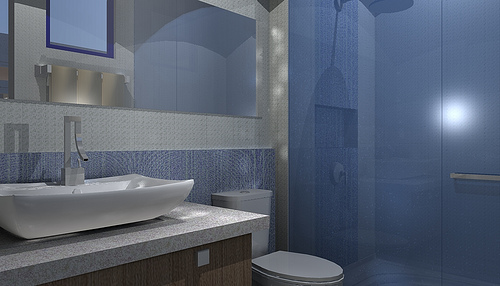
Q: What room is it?
A: It is a bathroom.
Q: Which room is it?
A: It is a bathroom.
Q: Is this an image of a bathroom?
A: Yes, it is showing a bathroom.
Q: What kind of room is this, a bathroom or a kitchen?
A: It is a bathroom.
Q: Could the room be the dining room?
A: No, it is the bathroom.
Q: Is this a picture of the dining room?
A: No, the picture is showing the bathroom.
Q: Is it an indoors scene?
A: Yes, it is indoors.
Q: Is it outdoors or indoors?
A: It is indoors.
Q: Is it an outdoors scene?
A: No, it is indoors.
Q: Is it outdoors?
A: No, it is indoors.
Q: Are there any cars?
A: No, there are no cars.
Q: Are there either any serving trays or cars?
A: No, there are no cars or serving trays.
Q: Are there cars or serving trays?
A: No, there are no cars or serving trays.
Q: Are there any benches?
A: No, there are no benches.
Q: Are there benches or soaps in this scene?
A: No, there are no benches or soaps.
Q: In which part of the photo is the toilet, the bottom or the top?
A: The toilet is in the bottom of the image.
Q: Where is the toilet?
A: The toilet is in the bathroom.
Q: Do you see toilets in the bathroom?
A: Yes, there is a toilet in the bathroom.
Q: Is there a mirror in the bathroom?
A: No, there is a toilet in the bathroom.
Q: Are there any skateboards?
A: No, there are no skateboards.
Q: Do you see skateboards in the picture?
A: No, there are no skateboards.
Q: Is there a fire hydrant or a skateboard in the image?
A: No, there are no skateboards or fire hydrants.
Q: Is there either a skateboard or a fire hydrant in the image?
A: No, there are no skateboards or fire hydrants.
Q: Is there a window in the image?
A: Yes, there is a window.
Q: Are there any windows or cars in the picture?
A: Yes, there is a window.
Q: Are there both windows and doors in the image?
A: Yes, there are both a window and a door.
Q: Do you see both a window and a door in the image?
A: Yes, there are both a window and a door.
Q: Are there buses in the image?
A: No, there are no buses.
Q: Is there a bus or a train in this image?
A: No, there are no buses or trains.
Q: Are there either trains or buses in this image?
A: No, there are no buses or trains.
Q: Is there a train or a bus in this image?
A: No, there are no buses or trains.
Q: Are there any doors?
A: Yes, there is a door.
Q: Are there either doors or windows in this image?
A: Yes, there is a door.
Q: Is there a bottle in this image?
A: No, there are no bottles.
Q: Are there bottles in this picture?
A: No, there are no bottles.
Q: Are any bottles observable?
A: No, there are no bottles.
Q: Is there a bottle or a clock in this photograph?
A: No, there are no bottles or clocks.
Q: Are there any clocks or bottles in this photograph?
A: No, there are no bottles or clocks.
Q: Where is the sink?
A: The sink is in the bathroom.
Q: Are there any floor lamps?
A: No, there are no floor lamps.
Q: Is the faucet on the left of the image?
A: Yes, the faucet is on the left of the image.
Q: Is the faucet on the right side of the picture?
A: No, the faucet is on the left of the image.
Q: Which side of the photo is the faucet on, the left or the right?
A: The faucet is on the left of the image.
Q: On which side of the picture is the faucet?
A: The faucet is on the left of the image.